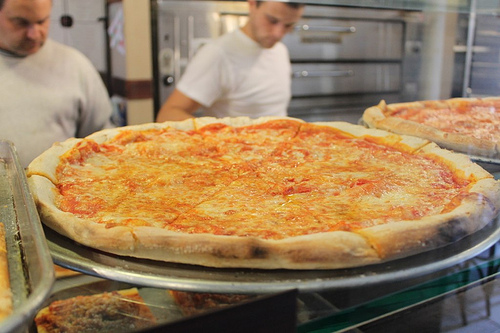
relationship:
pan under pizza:
[30, 225, 484, 292] [29, 114, 499, 269]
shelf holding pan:
[0, 134, 500, 330] [25, 182, 498, 294]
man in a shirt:
[2, 1, 124, 191] [0, 36, 112, 164]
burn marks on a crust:
[207, 237, 270, 261] [129, 222, 376, 267]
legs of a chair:
[452, 249, 492, 325] [450, 242, 493, 322]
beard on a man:
[245, 10, 281, 49] [151, 4, 301, 133]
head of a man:
[0, 0, 54, 56] [2, 1, 124, 191]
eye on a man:
[11, 16, 30, 32] [2, 1, 124, 191]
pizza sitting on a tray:
[29, 114, 499, 269] [20, 171, 498, 293]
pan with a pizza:
[30, 225, 499, 293] [29, 114, 499, 269]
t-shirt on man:
[172, 25, 278, 116] [151, 4, 301, 133]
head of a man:
[243, 0, 300, 46] [151, 4, 301, 133]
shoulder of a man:
[173, 33, 239, 109] [151, 4, 301, 133]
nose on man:
[265, 25, 283, 44] [151, 4, 301, 133]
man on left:
[151, 4, 301, 133] [159, 3, 499, 331]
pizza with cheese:
[19, 114, 499, 269] [101, 174, 221, 219]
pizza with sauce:
[19, 114, 499, 269] [276, 182, 315, 196]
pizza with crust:
[19, 114, 499, 269] [129, 222, 376, 267]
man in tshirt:
[151, 4, 301, 133] [174, 27, 298, 125]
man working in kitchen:
[151, 4, 301, 133] [5, 0, 495, 330]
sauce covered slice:
[47, 305, 95, 324] [42, 281, 157, 331]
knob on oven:
[163, 75, 176, 86] [161, 3, 439, 117]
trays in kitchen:
[453, 2, 494, 102] [5, 0, 495, 330]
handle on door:
[293, 67, 355, 79] [284, 60, 409, 104]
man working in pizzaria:
[2, 1, 124, 191] [4, 0, 499, 330]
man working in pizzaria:
[151, 4, 301, 133] [4, 0, 499, 330]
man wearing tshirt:
[151, 4, 301, 133] [174, 27, 298, 125]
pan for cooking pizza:
[1, 131, 61, 330] [29, 114, 499, 269]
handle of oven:
[293, 63, 363, 83] [161, 3, 439, 117]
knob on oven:
[155, 72, 183, 93] [161, 3, 439, 117]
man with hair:
[151, 4, 301, 133] [245, 16, 285, 46]